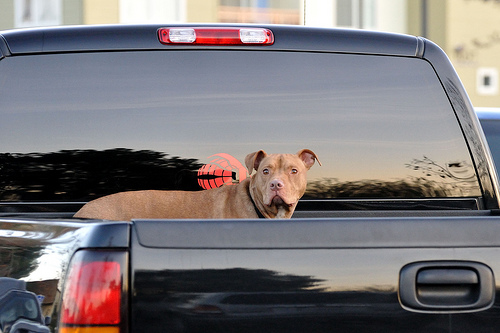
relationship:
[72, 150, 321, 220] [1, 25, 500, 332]
dog in a car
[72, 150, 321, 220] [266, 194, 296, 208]
dog has a mouth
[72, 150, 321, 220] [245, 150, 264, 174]
dog has an ear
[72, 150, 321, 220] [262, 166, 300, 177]
dog has eyes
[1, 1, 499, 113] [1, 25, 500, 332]
buildings behind car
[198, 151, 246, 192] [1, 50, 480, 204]
sticker on a window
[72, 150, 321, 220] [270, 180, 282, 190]
dog has a nose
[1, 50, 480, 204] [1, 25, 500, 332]
window on a car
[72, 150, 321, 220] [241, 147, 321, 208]
dog has a head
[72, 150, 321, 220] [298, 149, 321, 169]
dog has an ear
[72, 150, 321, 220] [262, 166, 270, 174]
dog has an eye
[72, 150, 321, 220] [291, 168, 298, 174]
dog has an eye